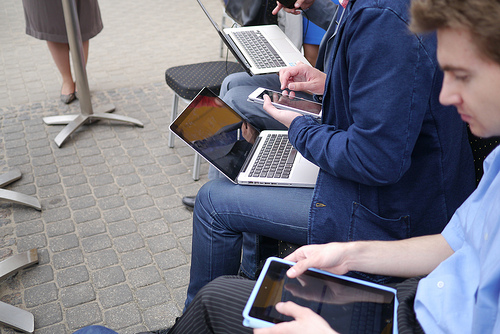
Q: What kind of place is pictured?
A: It is a sidewalk.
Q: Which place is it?
A: It is a sidewalk.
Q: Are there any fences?
A: No, there are no fences.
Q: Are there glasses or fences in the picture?
A: No, there are no fences or glasses.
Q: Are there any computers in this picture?
A: Yes, there is a computer.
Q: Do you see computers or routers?
A: Yes, there is a computer.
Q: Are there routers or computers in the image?
A: Yes, there is a computer.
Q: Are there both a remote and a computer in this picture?
A: No, there is a computer but no remote controls.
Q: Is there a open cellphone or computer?
A: Yes, there is an open computer.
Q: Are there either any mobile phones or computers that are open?
A: Yes, the computer is open.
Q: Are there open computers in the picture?
A: Yes, there is an open computer.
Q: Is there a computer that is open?
A: Yes, there is a computer that is open.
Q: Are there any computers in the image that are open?
A: Yes, there is a computer that is open.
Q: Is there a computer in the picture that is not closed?
A: Yes, there is a open computer.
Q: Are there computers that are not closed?
A: Yes, there is a open computer.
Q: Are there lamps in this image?
A: No, there are no lamps.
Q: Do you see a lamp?
A: No, there are no lamps.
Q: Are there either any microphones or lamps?
A: No, there are no lamps or microphones.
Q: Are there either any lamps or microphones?
A: No, there are no lamps or microphones.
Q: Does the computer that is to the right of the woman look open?
A: Yes, the computer is open.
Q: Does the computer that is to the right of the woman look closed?
A: No, the computer is open.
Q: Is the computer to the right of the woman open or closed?
A: The computer is open.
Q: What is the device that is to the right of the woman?
A: The device is a computer.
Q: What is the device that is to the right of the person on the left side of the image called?
A: The device is a computer.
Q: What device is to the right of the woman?
A: The device is a computer.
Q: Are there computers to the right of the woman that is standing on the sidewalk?
A: Yes, there is a computer to the right of the woman.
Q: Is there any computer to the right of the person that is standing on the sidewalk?
A: Yes, there is a computer to the right of the woman.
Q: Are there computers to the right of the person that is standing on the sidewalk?
A: Yes, there is a computer to the right of the woman.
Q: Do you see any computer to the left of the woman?
A: No, the computer is to the right of the woman.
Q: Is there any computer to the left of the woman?
A: No, the computer is to the right of the woman.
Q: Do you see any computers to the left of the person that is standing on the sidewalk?
A: No, the computer is to the right of the woman.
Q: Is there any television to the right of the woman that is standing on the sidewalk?
A: No, there is a computer to the right of the woman.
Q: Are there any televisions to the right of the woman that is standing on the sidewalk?
A: No, there is a computer to the right of the woman.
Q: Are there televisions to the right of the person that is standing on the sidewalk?
A: No, there is a computer to the right of the woman.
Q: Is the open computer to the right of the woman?
A: Yes, the computer is to the right of the woman.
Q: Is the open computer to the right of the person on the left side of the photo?
A: Yes, the computer is to the right of the woman.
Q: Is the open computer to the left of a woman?
A: No, the computer is to the right of a woman.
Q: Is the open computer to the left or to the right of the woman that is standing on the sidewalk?
A: The computer is to the right of the woman.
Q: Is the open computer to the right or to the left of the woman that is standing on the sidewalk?
A: The computer is to the right of the woman.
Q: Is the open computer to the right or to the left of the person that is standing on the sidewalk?
A: The computer is to the right of the woman.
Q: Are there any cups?
A: No, there are no cups.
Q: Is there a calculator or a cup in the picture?
A: No, there are no cups or calculators.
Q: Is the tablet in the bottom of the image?
A: Yes, the tablet is in the bottom of the image.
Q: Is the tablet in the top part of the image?
A: No, the tablet is in the bottom of the image.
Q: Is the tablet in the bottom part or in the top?
A: The tablet is in the bottom of the image.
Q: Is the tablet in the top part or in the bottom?
A: The tablet is in the bottom of the image.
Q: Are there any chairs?
A: Yes, there is a chair.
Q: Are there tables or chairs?
A: Yes, there is a chair.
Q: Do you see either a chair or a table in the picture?
A: Yes, there is a chair.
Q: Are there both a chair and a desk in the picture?
A: No, there is a chair but no desks.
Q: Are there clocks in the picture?
A: No, there are no clocks.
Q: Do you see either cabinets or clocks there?
A: No, there are no clocks or cabinets.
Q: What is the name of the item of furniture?
A: The piece of furniture is a chair.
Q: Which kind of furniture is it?
A: The piece of furniture is a chair.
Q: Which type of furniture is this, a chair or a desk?
A: This is a chair.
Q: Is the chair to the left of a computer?
A: Yes, the chair is to the left of a computer.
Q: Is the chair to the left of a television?
A: No, the chair is to the left of a computer.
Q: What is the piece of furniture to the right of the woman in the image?
A: The piece of furniture is a chair.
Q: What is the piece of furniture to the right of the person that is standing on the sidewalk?
A: The piece of furniture is a chair.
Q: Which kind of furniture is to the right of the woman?
A: The piece of furniture is a chair.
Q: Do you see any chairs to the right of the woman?
A: Yes, there is a chair to the right of the woman.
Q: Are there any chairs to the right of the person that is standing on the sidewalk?
A: Yes, there is a chair to the right of the woman.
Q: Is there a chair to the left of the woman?
A: No, the chair is to the right of the woman.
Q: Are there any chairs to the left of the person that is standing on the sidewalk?
A: No, the chair is to the right of the woman.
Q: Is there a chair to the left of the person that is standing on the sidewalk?
A: No, the chair is to the right of the woman.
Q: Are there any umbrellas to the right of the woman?
A: No, there is a chair to the right of the woman.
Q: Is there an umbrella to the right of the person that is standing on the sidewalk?
A: No, there is a chair to the right of the woman.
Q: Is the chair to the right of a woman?
A: Yes, the chair is to the right of a woman.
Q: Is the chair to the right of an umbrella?
A: No, the chair is to the right of a woman.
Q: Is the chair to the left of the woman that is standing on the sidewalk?
A: No, the chair is to the right of the woman.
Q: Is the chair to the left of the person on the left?
A: No, the chair is to the right of the woman.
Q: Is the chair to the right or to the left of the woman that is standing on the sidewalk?
A: The chair is to the right of the woman.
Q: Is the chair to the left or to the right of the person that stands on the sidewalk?
A: The chair is to the right of the woman.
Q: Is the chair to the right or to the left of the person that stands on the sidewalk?
A: The chair is to the right of the woman.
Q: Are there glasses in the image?
A: No, there are no glasses.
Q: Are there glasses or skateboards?
A: No, there are no glasses or skateboards.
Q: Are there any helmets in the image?
A: No, there are no helmets.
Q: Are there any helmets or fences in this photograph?
A: No, there are no helmets or fences.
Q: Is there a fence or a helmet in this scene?
A: No, there are no helmets or fences.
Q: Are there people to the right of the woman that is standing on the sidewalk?
A: Yes, there is a person to the right of the woman.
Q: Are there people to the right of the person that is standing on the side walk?
A: Yes, there is a person to the right of the woman.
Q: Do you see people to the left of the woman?
A: No, the person is to the right of the woman.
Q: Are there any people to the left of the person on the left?
A: No, the person is to the right of the woman.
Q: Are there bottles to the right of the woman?
A: No, there is a person to the right of the woman.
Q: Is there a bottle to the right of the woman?
A: No, there is a person to the right of the woman.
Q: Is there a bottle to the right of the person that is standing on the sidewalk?
A: No, there is a person to the right of the woman.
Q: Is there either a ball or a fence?
A: No, there are no fences or balls.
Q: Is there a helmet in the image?
A: No, there are no helmets.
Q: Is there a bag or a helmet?
A: No, there are no helmets or bags.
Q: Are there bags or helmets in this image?
A: No, there are no helmets or bags.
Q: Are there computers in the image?
A: Yes, there is a computer.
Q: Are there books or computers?
A: Yes, there is a computer.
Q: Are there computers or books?
A: Yes, there is a computer.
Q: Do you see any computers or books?
A: Yes, there is a computer.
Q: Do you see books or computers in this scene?
A: Yes, there is a computer.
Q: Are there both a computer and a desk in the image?
A: No, there is a computer but no desks.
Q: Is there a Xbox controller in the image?
A: No, there are no Xbox controllers.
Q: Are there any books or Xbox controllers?
A: No, there are no Xbox controllers or books.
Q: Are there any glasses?
A: No, there are no glasses.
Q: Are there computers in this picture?
A: Yes, there is a computer.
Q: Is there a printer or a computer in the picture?
A: Yes, there is a computer.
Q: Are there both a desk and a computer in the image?
A: No, there is a computer but no desks.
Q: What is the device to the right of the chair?
A: The device is a computer.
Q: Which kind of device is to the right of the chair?
A: The device is a computer.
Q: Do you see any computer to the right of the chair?
A: Yes, there is a computer to the right of the chair.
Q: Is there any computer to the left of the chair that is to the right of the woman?
A: No, the computer is to the right of the chair.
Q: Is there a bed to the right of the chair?
A: No, there is a computer to the right of the chair.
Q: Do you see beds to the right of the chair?
A: No, there is a computer to the right of the chair.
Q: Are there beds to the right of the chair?
A: No, there is a computer to the right of the chair.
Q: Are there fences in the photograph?
A: No, there are no fences.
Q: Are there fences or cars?
A: No, there are no fences or cars.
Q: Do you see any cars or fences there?
A: No, there are no fences or cars.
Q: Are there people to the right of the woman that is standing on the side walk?
A: Yes, there is a person to the right of the woman.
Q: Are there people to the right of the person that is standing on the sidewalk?
A: Yes, there is a person to the right of the woman.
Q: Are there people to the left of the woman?
A: No, the person is to the right of the woman.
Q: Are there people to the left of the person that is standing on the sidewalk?
A: No, the person is to the right of the woman.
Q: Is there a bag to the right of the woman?
A: No, there is a person to the right of the woman.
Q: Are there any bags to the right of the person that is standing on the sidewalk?
A: No, there is a person to the right of the woman.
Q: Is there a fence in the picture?
A: No, there are no fences.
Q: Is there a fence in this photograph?
A: No, there are no fences.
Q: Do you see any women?
A: Yes, there is a woman.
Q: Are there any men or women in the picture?
A: Yes, there is a woman.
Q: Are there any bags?
A: No, there are no bags.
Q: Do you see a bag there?
A: No, there are no bags.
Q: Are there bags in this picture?
A: No, there are no bags.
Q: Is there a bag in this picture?
A: No, there are no bags.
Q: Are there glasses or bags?
A: No, there are no bags or glasses.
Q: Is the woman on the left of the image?
A: Yes, the woman is on the left of the image.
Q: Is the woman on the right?
A: No, the woman is on the left of the image.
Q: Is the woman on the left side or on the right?
A: The woman is on the left of the image.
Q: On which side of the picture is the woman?
A: The woman is on the left of the image.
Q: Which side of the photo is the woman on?
A: The woman is on the left of the image.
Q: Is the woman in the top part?
A: Yes, the woman is in the top of the image.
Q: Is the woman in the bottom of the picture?
A: No, the woman is in the top of the image.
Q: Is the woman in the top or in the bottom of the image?
A: The woman is in the top of the image.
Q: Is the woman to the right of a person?
A: No, the woman is to the left of a person.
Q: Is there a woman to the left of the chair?
A: Yes, there is a woman to the left of the chair.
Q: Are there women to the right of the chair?
A: No, the woman is to the left of the chair.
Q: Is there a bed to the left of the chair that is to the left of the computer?
A: No, there is a woman to the left of the chair.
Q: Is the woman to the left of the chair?
A: Yes, the woman is to the left of the chair.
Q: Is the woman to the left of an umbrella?
A: No, the woman is to the left of the chair.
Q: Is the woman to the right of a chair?
A: No, the woman is to the left of a chair.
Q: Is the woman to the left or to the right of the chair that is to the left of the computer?
A: The woman is to the left of the chair.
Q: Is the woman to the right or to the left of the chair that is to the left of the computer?
A: The woman is to the left of the chair.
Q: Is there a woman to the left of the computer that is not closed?
A: Yes, there is a woman to the left of the computer.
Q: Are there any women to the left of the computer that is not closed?
A: Yes, there is a woman to the left of the computer.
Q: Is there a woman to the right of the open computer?
A: No, the woman is to the left of the computer.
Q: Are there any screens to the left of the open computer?
A: No, there is a woman to the left of the computer.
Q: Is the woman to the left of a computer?
A: Yes, the woman is to the left of a computer.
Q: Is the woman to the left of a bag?
A: No, the woman is to the left of a computer.